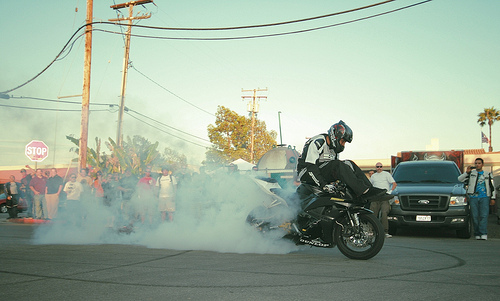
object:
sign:
[20, 135, 58, 165]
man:
[290, 115, 403, 207]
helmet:
[323, 116, 360, 154]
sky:
[339, 40, 383, 76]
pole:
[70, 4, 102, 182]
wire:
[212, 21, 263, 33]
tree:
[193, 102, 284, 179]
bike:
[234, 153, 395, 273]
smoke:
[0, 89, 313, 257]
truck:
[369, 156, 476, 241]